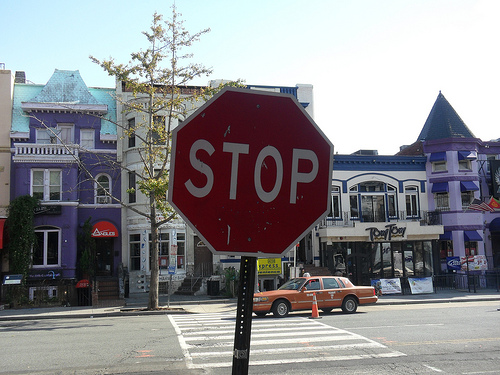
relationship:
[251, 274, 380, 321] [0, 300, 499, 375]
taxi on street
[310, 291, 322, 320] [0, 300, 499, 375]
cone on street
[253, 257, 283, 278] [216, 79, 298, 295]
sign over building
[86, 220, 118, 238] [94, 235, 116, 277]
awning over entrance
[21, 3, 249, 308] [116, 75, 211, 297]
tree front building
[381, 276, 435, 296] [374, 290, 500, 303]
sign on sidewalk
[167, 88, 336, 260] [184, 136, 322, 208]
sign says stop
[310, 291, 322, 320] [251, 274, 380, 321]
cone next taxi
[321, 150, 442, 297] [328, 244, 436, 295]
business has storefront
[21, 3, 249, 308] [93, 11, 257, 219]
tree has leaves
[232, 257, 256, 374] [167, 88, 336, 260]
pole supporting sign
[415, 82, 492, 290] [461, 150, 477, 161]
building has awning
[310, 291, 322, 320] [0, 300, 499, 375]
cone in street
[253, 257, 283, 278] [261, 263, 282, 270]
sign says express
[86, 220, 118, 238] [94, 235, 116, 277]
awning above door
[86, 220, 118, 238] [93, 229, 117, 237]
awning has designs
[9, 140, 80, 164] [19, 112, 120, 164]
balcony on top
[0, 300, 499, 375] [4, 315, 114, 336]
street has shadows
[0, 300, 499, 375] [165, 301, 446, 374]
street has lines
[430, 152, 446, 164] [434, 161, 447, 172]
awning has windows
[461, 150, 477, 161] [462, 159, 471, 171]
awning have windows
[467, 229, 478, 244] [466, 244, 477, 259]
awning have windows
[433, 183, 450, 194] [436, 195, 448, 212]
awning have windows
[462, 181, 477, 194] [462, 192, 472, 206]
awning have windows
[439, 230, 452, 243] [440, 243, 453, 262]
awning have windows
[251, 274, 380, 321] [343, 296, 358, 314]
taxi has tire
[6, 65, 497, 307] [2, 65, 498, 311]
row of establishments